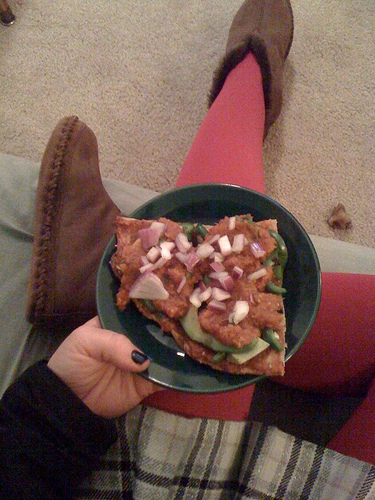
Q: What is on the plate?
A: Pizza.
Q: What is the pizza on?
A: A plate.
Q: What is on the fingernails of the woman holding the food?
A: Nail polish.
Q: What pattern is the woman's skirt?
A: Plaid.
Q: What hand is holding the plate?
A: Left.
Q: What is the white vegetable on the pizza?
A: Onions.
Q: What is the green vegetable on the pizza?
A: Peppers.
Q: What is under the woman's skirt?
A: Tights.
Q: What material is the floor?
A: Carpet.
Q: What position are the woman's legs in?
A: Crossed.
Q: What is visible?
A: The slice of pizza.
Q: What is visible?
A: The slice of pizza.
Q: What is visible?
A: The slice of pizza.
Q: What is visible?
A: The slice of pizza.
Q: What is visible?
A: The slice of pizza.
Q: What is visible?
A: The slice of pizza.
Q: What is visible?
A: The slice of pizza.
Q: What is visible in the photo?
A: A plate.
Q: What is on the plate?
A: Pizza.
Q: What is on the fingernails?
A: Polish.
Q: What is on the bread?
A: Onion and peppers.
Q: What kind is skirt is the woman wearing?
A: Plaid.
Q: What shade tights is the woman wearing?
A: Red.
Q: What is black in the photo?
A: The persons sleeves.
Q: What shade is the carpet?
A: Tan.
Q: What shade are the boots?
A: Brown.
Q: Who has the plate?
A: A woman.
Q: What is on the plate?
A: Pizza.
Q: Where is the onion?
A: On the pizza.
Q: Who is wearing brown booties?
A: The woman.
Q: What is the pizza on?
A: A black plate.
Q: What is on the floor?
A: Food.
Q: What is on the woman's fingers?
A: Black nail polish.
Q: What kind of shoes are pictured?
A: Moccasins.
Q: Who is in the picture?
A: A woman.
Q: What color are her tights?
A: Pink.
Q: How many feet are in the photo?
A: Two.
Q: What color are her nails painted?
A: Black.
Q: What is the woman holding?
A: A plate.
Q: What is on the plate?
A: Food.